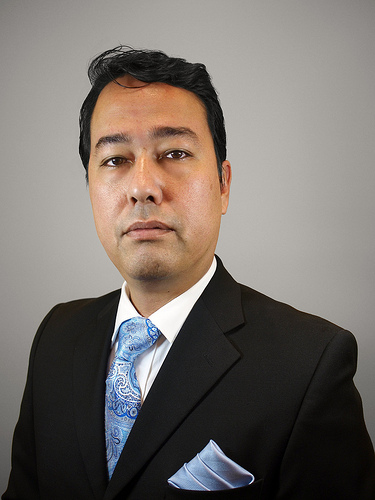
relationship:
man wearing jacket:
[0, 45, 375, 500] [0, 253, 375, 500]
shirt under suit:
[106, 254, 221, 477] [1, 252, 363, 497]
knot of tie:
[115, 317, 161, 362] [103, 317, 160, 479]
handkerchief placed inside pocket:
[167, 439, 255, 491] [161, 478, 258, 498]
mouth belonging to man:
[119, 218, 176, 241] [0, 45, 375, 500]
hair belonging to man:
[77, 42, 229, 187] [0, 45, 375, 500]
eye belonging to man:
[156, 147, 194, 161] [0, 45, 375, 500]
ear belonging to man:
[218, 159, 232, 215] [0, 45, 375, 500]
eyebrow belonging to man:
[147, 122, 199, 142] [0, 45, 375, 500]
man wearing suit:
[0, 45, 375, 500] [1, 252, 363, 497]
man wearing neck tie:
[0, 45, 375, 500] [104, 317, 162, 481]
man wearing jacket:
[0, 45, 375, 500] [100, 349, 285, 437]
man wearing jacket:
[89, 51, 294, 350] [73, 326, 338, 469]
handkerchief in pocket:
[167, 439, 255, 491] [245, 450, 295, 490]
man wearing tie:
[0, 45, 375, 500] [75, 314, 193, 463]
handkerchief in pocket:
[167, 434, 257, 487] [162, 486, 268, 491]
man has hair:
[0, 45, 375, 500] [77, 42, 229, 187]